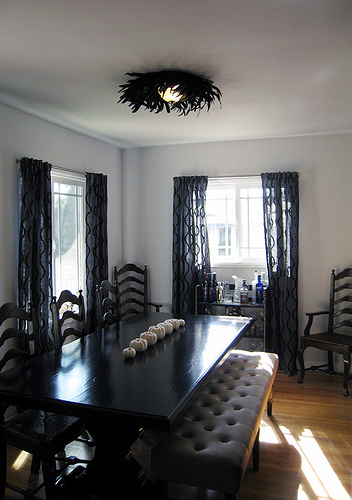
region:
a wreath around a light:
[114, 67, 221, 117]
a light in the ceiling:
[156, 82, 186, 104]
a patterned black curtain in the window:
[170, 173, 214, 312]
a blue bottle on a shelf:
[253, 272, 264, 303]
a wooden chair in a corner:
[108, 257, 165, 318]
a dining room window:
[49, 172, 92, 323]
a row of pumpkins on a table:
[122, 315, 187, 357]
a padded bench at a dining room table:
[144, 342, 284, 498]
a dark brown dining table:
[1, 310, 254, 498]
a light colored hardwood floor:
[0, 371, 349, 498]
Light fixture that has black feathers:
[113, 62, 230, 114]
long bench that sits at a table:
[205, 347, 278, 481]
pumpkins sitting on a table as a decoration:
[104, 313, 201, 360]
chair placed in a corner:
[294, 247, 350, 400]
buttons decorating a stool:
[212, 346, 288, 458]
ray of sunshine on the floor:
[3, 443, 37, 484]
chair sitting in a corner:
[107, 254, 165, 325]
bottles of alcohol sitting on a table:
[193, 263, 275, 310]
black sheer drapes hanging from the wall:
[256, 168, 314, 387]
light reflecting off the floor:
[262, 411, 351, 499]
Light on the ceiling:
[104, 55, 219, 119]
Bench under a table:
[150, 318, 278, 482]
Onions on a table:
[112, 310, 188, 373]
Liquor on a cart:
[197, 254, 274, 307]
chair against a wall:
[292, 248, 346, 396]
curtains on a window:
[13, 149, 115, 326]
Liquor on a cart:
[199, 261, 265, 308]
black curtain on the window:
[259, 163, 307, 370]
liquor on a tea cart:
[198, 260, 278, 351]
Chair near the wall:
[102, 259, 173, 323]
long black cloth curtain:
[15, 157, 53, 300]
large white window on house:
[47, 166, 86, 288]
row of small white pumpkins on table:
[115, 309, 195, 361]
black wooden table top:
[104, 368, 179, 416]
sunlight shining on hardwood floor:
[273, 419, 343, 498]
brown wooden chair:
[296, 263, 350, 393]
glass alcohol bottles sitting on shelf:
[184, 269, 269, 311]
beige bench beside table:
[154, 342, 282, 477]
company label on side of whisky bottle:
[240, 290, 248, 303]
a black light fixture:
[118, 68, 223, 118]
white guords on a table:
[123, 317, 184, 356]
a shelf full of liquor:
[197, 263, 267, 353]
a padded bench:
[151, 348, 280, 492]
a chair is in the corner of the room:
[112, 261, 161, 314]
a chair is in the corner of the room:
[296, 268, 351, 392]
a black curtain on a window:
[86, 235, 108, 327]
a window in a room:
[205, 235, 265, 267]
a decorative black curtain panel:
[174, 170, 216, 306]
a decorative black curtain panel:
[260, 168, 301, 374]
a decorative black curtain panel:
[18, 158, 65, 357]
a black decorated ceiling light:
[116, 66, 226, 122]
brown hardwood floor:
[237, 368, 351, 498]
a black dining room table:
[1, 299, 256, 479]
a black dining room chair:
[110, 263, 162, 316]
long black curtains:
[17, 154, 58, 332]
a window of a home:
[187, 186, 271, 265]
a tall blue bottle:
[255, 273, 262, 304]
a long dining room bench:
[155, 350, 288, 498]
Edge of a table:
[148, 403, 188, 434]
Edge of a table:
[146, 399, 188, 433]